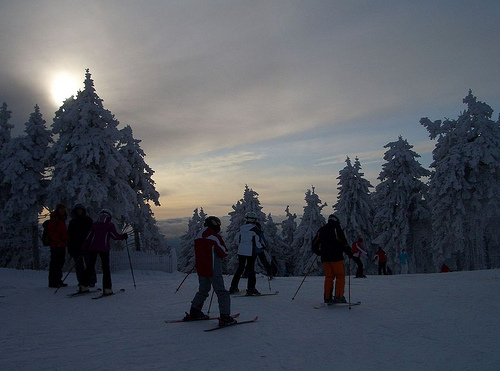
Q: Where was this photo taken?
A: On a mountain.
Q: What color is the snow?
A: White.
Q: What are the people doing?
A: Skiing.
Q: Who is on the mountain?
A: Skiers.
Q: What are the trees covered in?
A: Snow.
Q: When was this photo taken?
A: Daytime.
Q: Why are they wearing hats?
A: To stay warm.